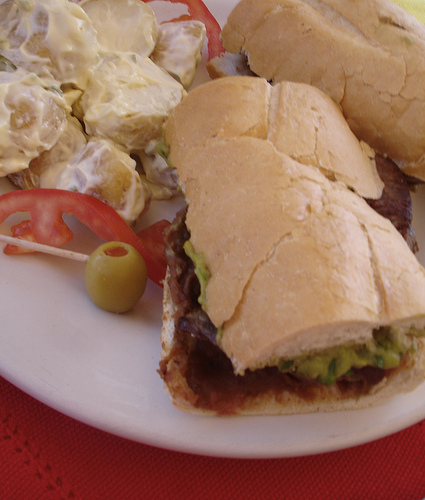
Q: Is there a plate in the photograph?
A: Yes, there is a plate.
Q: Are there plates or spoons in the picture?
A: Yes, there is a plate.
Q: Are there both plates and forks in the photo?
A: No, there is a plate but no forks.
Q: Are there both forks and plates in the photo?
A: No, there is a plate but no forks.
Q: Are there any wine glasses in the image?
A: No, there are no wine glasses.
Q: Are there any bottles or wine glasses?
A: No, there are no wine glasses or bottles.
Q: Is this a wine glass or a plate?
A: This is a plate.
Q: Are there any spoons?
A: No, there are no spoons.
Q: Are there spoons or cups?
A: No, there are no spoons or cups.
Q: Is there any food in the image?
A: Yes, there is food.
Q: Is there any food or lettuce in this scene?
A: Yes, there is food.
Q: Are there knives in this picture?
A: No, there are no knives.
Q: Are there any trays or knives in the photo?
A: No, there are no knives or trays.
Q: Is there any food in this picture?
A: Yes, there is food.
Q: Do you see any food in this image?
A: Yes, there is food.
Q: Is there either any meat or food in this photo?
A: Yes, there is food.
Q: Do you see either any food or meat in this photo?
A: Yes, there is food.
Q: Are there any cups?
A: No, there are no cups.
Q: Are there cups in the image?
A: No, there are no cups.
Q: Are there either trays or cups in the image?
A: No, there are no cups or trays.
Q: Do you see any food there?
A: Yes, there is food.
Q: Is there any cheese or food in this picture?
A: Yes, there is food.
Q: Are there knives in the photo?
A: No, there are no knives.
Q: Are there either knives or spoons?
A: No, there are no knives or spoons.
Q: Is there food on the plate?
A: Yes, there is food on the plate.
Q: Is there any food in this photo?
A: Yes, there is food.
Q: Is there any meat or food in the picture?
A: Yes, there is food.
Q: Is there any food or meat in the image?
A: Yes, there is food.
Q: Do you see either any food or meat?
A: Yes, there is food.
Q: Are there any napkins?
A: No, there are no napkins.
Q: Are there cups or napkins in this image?
A: No, there are no napkins or cups.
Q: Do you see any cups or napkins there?
A: No, there are no napkins or cups.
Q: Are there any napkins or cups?
A: No, there are no napkins or cups.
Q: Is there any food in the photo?
A: Yes, there is food.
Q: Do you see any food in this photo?
A: Yes, there is food.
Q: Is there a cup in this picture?
A: No, there are no cups.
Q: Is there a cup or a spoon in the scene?
A: No, there are no cups or spoons.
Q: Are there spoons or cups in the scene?
A: No, there are no cups or spoons.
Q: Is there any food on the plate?
A: Yes, there is food on the plate.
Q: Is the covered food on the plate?
A: Yes, the food is on the plate.